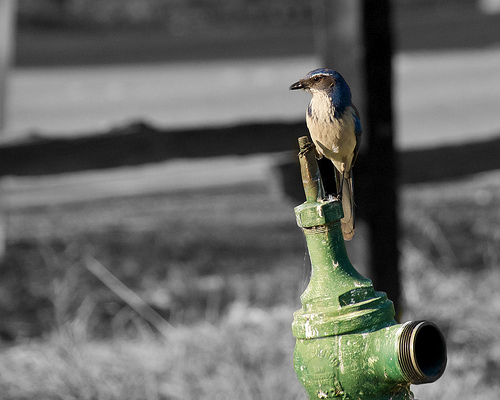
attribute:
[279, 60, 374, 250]
bird — blue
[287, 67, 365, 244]
bird — blue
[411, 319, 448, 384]
opening — small 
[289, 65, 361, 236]
jay — bully, blue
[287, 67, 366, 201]
bird — blue, small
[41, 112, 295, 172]
fence — wooden, horizontal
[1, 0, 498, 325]
fence — blurry, wooden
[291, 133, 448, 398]
hydrant — green, old